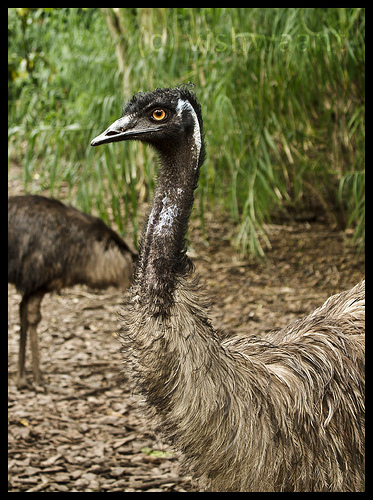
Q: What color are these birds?
A: Brown.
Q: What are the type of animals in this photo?
A: Birds.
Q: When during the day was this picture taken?
A: During the daytime.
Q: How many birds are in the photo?
A: Two.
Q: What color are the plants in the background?
A: Green.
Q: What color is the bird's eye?
A: Gold.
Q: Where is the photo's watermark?
A: On the upper right.